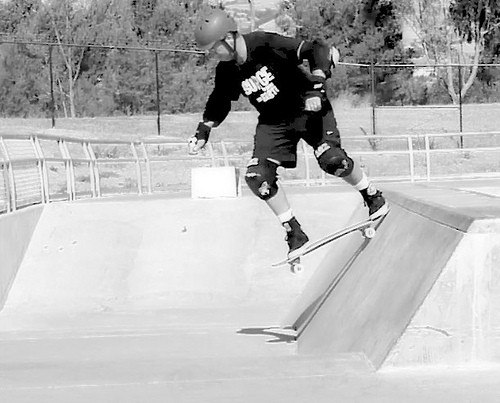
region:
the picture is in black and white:
[5, 0, 497, 396]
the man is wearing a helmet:
[181, 13, 263, 61]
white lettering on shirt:
[233, 60, 322, 115]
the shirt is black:
[175, 53, 360, 111]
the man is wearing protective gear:
[161, 16, 390, 253]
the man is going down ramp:
[160, 10, 457, 274]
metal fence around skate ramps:
[3, 116, 497, 211]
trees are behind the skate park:
[0, 0, 494, 150]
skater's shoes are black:
[253, 191, 423, 242]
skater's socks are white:
[250, 173, 384, 228]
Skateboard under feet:
[266, 202, 387, 290]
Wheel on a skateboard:
[281, 262, 313, 285]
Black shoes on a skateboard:
[258, 180, 409, 247]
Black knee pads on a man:
[226, 152, 371, 210]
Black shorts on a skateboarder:
[237, 112, 359, 169]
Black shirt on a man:
[191, 43, 356, 158]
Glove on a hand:
[175, 118, 226, 164]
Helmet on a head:
[187, 9, 254, 66]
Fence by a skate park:
[63, 95, 276, 205]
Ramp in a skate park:
[248, 191, 455, 362]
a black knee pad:
[241, 152, 283, 201]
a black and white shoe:
[278, 211, 310, 266]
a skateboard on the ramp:
[261, 210, 389, 276]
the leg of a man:
[303, 103, 378, 198]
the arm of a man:
[265, 27, 335, 87]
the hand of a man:
[301, 91, 326, 114]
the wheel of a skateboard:
[289, 259, 308, 276]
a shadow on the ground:
[233, 210, 388, 351]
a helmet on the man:
[191, 10, 241, 57]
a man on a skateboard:
[181, 9, 409, 261]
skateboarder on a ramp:
[160, 1, 402, 282]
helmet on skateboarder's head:
[185, 2, 254, 69]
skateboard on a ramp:
[274, 211, 379, 276]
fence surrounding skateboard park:
[2, 124, 182, 203]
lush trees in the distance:
[8, 7, 168, 39]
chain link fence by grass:
[2, 32, 198, 137]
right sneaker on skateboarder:
[275, 215, 312, 260]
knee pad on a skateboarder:
[310, 145, 360, 176]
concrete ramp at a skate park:
[385, 166, 495, 376]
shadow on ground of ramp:
[225, 273, 342, 353]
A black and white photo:
[51, 17, 449, 332]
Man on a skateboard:
[111, 16, 402, 336]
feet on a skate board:
[245, 196, 407, 300]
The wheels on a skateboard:
[277, 248, 323, 290]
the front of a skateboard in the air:
[261, 200, 367, 312]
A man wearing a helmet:
[156, 13, 283, 97]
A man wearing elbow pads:
[158, 20, 354, 149]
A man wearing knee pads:
[168, 18, 399, 282]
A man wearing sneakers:
[148, 33, 414, 293]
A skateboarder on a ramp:
[123, 26, 410, 297]